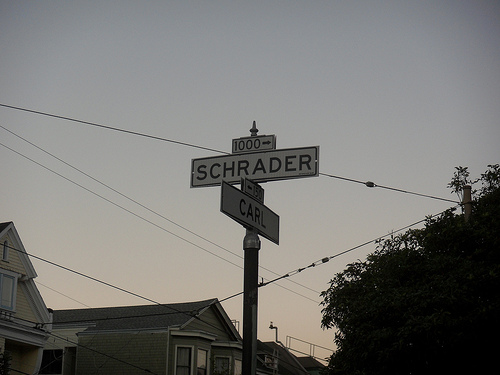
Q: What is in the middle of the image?
A: Set of four road signs.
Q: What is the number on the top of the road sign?
A: 1000.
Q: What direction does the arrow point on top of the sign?
A: To the right.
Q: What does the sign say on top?
A: Schrader.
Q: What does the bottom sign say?
A: Carl.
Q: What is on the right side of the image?
A: A group of trees.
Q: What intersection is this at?
A: Schrader and Carl.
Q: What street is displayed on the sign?
A: Schrader.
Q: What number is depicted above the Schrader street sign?
A: 1000.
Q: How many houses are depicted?
A: 3.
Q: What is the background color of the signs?
A: White.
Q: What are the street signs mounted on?
A: Pole.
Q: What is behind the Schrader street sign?
A: Wires.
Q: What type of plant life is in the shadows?
A: Trees.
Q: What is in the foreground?
A: Tree.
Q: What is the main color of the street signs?
A: White.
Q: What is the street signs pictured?
A: Schrader and CArl.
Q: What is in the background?
A: Houses.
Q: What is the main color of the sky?
A: Gray.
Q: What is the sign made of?
A: Metal.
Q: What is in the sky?
A: Wires.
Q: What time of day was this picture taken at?
A: Sunset.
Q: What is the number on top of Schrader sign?
A: 1000.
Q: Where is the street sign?
A: Behind houses.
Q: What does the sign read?
A: Schrader.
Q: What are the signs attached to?
A: Pole.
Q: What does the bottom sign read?
A: Carl.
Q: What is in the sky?
A: Power lines.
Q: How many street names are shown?
A: Two.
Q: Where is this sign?
A: On a post.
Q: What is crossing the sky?
A: Electrical wires.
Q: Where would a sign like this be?
A: On a corner.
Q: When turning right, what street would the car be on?
A: Carl.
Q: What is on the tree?
A: Leaves.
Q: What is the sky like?
A: Gray.